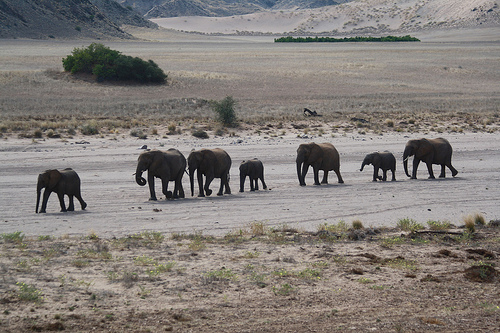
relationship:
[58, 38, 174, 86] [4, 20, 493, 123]
bush are on desert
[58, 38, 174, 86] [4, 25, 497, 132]
bush are on desert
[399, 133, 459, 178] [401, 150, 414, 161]
elephant has tusk